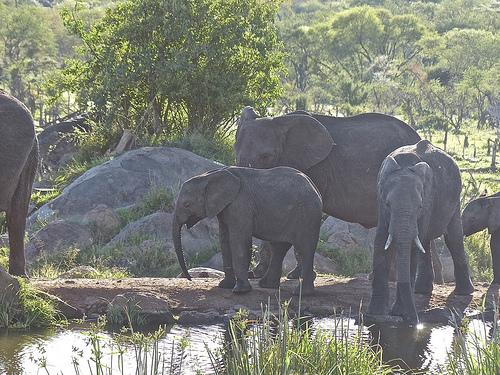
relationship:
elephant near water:
[172, 164, 324, 295] [1, 321, 498, 373]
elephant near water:
[369, 138, 472, 312] [1, 321, 498, 373]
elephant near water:
[235, 105, 434, 296] [1, 321, 498, 373]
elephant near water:
[0, 78, 38, 279] [1, 321, 498, 373]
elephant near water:
[462, 193, 499, 289] [1, 321, 498, 373]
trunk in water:
[396, 241, 420, 326] [1, 321, 498, 373]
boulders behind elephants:
[24, 152, 476, 279] [172, 105, 499, 316]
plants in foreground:
[37, 301, 499, 375] [1, 264, 498, 374]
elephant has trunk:
[172, 164, 324, 295] [172, 219, 193, 281]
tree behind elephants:
[60, 0, 283, 139] [172, 105, 499, 316]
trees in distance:
[297, 7, 499, 129] [0, 0, 498, 171]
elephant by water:
[172, 164, 324, 295] [1, 321, 498, 373]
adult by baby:
[235, 105, 434, 296] [172, 164, 324, 295]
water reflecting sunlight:
[1, 321, 498, 373] [26, 325, 234, 374]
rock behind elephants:
[317, 215, 469, 262] [172, 105, 499, 316]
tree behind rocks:
[60, 0, 283, 139] [24, 152, 476, 279]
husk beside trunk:
[413, 235, 426, 254] [396, 241, 420, 326]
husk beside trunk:
[383, 234, 393, 249] [396, 241, 420, 326]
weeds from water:
[37, 301, 499, 375] [1, 321, 498, 373]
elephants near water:
[172, 105, 499, 316] [1, 321, 498, 373]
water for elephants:
[1, 321, 498, 373] [172, 105, 499, 316]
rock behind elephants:
[24, 152, 476, 279] [172, 105, 499, 316]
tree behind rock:
[60, 0, 283, 139] [24, 152, 476, 279]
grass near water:
[37, 301, 499, 375] [1, 321, 498, 373]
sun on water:
[415, 321, 426, 331] [1, 321, 498, 373]